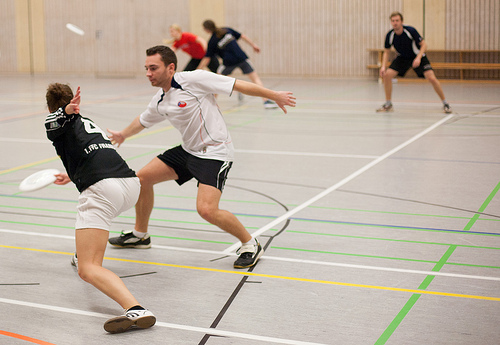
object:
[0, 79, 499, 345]
grey floor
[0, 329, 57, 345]
painted lines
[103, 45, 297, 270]
man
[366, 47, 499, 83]
bleachers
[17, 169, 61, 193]
frisbee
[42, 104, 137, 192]
shirt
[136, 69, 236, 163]
shirt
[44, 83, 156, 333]
girl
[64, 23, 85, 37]
frisbee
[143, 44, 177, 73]
hair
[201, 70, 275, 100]
arms